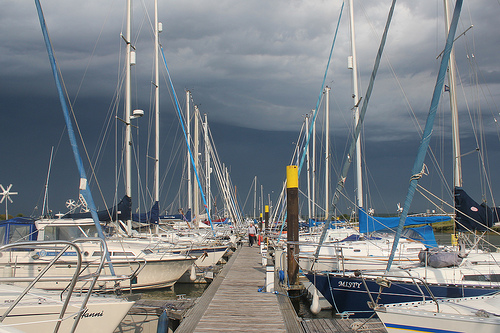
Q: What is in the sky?
A: Large clouds.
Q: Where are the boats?
A: At the marina.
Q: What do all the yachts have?
A: Masts.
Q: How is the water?
A: Calm.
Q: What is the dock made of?
A: Wood.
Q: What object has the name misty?
A: A yacht.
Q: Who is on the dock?
A: A person.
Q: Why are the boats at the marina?
A: To dock.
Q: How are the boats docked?
A: With tied rope.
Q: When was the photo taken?
A: During the daytime.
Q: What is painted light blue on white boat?
A: A sail.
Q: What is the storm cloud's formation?
A: White and gray.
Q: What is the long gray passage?
A: Wooden pier.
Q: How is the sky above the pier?
A: Gray and stormy.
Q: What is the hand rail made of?
A: Silver metal.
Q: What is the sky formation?
A: Dark clouds.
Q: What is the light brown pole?
A: A wooden boardwalk.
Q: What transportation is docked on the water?
A: Row of boats.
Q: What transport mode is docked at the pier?
A: Boats.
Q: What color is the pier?
A: Brown.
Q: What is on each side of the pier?
A: Boats.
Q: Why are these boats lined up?
A: They are docked.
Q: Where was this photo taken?
A: At a pier.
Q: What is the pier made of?
A: Wood.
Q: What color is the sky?
A: Blue.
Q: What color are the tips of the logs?
A: Yellow.